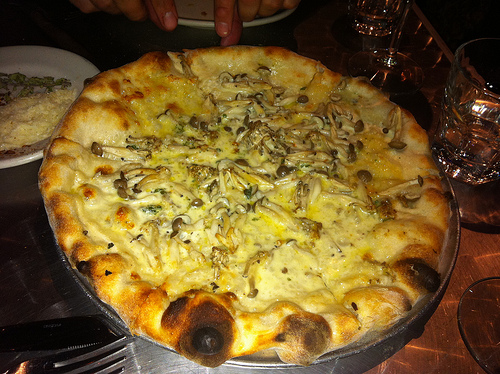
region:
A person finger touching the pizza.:
[148, 0, 244, 51]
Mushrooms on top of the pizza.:
[173, 111, 333, 218]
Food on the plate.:
[5, 61, 60, 145]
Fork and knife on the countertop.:
[14, 315, 93, 372]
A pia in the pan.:
[79, 94, 448, 322]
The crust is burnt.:
[166, 303, 243, 370]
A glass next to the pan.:
[430, 57, 499, 161]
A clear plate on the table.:
[456, 284, 491, 356]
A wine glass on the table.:
[364, 13, 424, 103]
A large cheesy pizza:
[32, 38, 474, 373]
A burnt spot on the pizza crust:
[152, 281, 255, 368]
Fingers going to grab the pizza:
[117, 3, 300, 52]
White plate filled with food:
[0, 36, 96, 158]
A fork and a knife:
[0, 308, 128, 372]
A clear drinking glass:
[428, 41, 498, 189]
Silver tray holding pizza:
[30, 40, 469, 369]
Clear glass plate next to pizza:
[451, 263, 496, 370]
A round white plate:
[140, 0, 313, 33]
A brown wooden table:
[385, 195, 498, 372]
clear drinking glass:
[431, 37, 497, 187]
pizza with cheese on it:
[33, 44, 460, 369]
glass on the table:
[328, 2, 421, 72]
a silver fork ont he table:
[32, 331, 155, 371]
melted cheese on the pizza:
[124, 52, 435, 370]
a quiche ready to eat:
[66, 47, 426, 349]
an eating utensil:
[21, 340, 136, 370]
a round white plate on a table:
[2, 43, 99, 165]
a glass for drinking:
[435, 26, 491, 187]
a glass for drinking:
[357, 8, 407, 83]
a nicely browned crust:
[58, 46, 448, 336]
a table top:
[10, 13, 498, 361]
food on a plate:
[5, 68, 82, 150]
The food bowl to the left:
[0, 39, 102, 187]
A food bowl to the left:
[2, 32, 99, 164]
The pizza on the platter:
[29, 32, 469, 341]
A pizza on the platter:
[29, 42, 479, 369]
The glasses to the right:
[357, 11, 498, 180]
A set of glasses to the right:
[346, 4, 498, 192]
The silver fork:
[12, 336, 133, 369]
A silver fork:
[7, 330, 130, 372]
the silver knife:
[1, 312, 116, 369]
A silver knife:
[3, 307, 126, 350]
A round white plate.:
[0, 45, 97, 171]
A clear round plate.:
[457, 273, 498, 373]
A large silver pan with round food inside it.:
[39, 43, 461, 372]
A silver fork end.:
[0, 331, 127, 372]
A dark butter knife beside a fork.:
[0, 316, 117, 354]